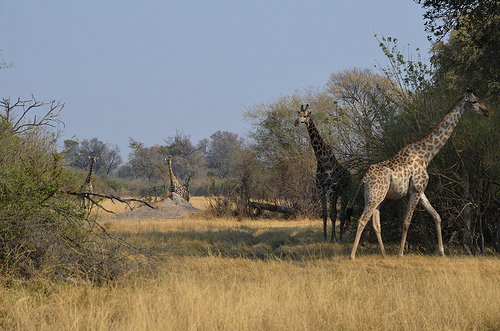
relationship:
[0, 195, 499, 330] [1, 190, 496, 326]
grass standing in field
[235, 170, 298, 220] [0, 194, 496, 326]
tree lying on ground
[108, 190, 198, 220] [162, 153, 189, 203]
rock sitting in front of giraffe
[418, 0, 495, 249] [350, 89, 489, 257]
mountain towering above giraffe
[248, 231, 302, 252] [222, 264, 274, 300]
shadow on ground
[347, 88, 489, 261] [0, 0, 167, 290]
animal standing in forest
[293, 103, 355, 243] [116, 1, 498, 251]
animal standing in forest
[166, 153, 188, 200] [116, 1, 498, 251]
animal standing in forest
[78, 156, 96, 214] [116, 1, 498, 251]
animal standing in forest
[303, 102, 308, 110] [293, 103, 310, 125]
horn on head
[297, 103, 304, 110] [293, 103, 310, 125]
horn on head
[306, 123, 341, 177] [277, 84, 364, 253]
neck on giraffe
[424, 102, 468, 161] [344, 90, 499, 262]
neck on giraffe